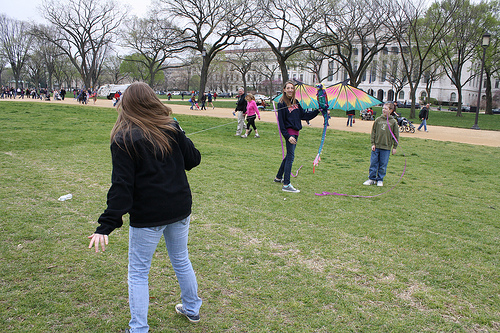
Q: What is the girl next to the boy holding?
A: Kite.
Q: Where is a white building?
A: Behind trees.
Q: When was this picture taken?
A: Daytime.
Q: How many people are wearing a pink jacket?
A: One.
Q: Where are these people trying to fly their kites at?
A: Large grass area.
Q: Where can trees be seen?
A: Other side of walking path.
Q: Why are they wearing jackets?
A: Cold out.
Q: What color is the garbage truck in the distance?
A: White.